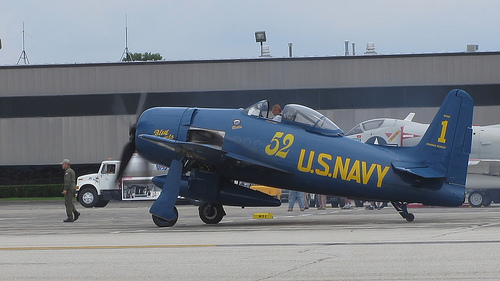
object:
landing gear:
[144, 165, 279, 227]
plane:
[341, 110, 498, 207]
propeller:
[104, 75, 150, 187]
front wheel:
[151, 202, 180, 228]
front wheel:
[195, 198, 226, 226]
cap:
[63, 158, 80, 165]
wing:
[134, 129, 289, 180]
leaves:
[143, 53, 162, 60]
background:
[2, 2, 498, 39]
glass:
[269, 92, 337, 127]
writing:
[248, 125, 420, 211]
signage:
[297, 140, 389, 189]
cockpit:
[249, 95, 336, 135]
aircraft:
[115, 87, 475, 226]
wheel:
[405, 208, 416, 220]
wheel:
[74, 185, 100, 207]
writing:
[435, 119, 447, 143]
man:
[58, 160, 81, 223]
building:
[0, 42, 499, 187]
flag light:
[255, 30, 264, 57]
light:
[465, 42, 481, 55]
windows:
[5, 158, 61, 188]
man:
[271, 102, 286, 122]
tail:
[419, 90, 477, 173]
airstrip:
[0, 200, 498, 279]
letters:
[369, 162, 390, 188]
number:
[265, 131, 292, 161]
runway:
[0, 200, 499, 279]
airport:
[1, 14, 497, 281]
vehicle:
[72, 152, 129, 224]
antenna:
[12, 27, 36, 67]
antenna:
[115, 18, 140, 65]